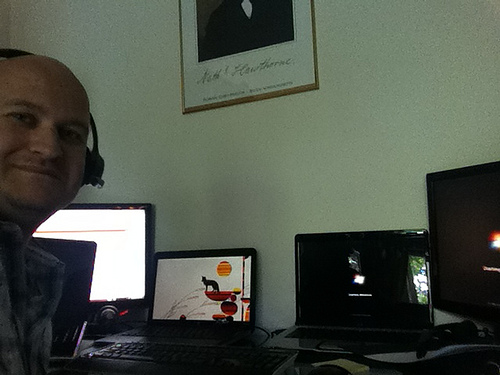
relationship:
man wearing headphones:
[4, 40, 87, 373] [1, 49, 105, 186]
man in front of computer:
[0, 40, 104, 375] [120, 237, 279, 358]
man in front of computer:
[0, 40, 104, 375] [271, 227, 447, 362]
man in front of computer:
[0, 40, 104, 375] [41, 218, 150, 365]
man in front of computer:
[0, 40, 104, 375] [35, 207, 150, 363]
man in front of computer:
[0, 40, 104, 375] [144, 247, 268, 372]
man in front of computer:
[0, 40, 104, 375] [279, 229, 457, 373]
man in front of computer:
[0, 40, 104, 375] [269, 222, 441, 358]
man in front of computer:
[0, 40, 104, 375] [92, 240, 262, 373]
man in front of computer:
[0, 40, 104, 375] [433, 171, 498, 323]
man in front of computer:
[0, 40, 104, 375] [254, 221, 439, 357]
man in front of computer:
[0, 40, 104, 375] [95, 243, 260, 350]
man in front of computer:
[0, 40, 104, 375] [33, 202, 153, 325]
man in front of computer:
[0, 40, 104, 375] [23, 236, 97, 363]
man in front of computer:
[0, 40, 104, 375] [426, 161, 498, 321]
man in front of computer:
[0, 40, 104, 375] [47, 189, 161, 343]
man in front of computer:
[0, 40, 104, 375] [274, 229, 416, 346]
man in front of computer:
[0, 40, 104, 375] [148, 234, 278, 366]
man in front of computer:
[0, 40, 104, 375] [408, 179, 485, 329]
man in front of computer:
[0, 40, 104, 375] [2, 200, 158, 353]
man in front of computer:
[0, 40, 104, 375] [115, 240, 272, 372]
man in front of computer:
[0, 40, 104, 375] [408, 157, 484, 372]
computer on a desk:
[262, 229, 435, 354] [27, 328, 489, 373]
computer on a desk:
[94, 247, 258, 347] [27, 328, 489, 373]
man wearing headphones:
[0, 40, 104, 375] [62, 81, 133, 200]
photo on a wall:
[178, 0, 320, 114] [350, 21, 495, 146]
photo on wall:
[178, 0, 320, 114] [0, 0, 499, 329]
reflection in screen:
[404, 252, 434, 310] [296, 229, 429, 326]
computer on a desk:
[264, 225, 439, 369] [13, 326, 498, 371]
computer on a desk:
[426, 156, 498, 363] [13, 326, 498, 371]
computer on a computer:
[83, 244, 261, 367] [25, 197, 155, 313]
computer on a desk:
[25, 197, 155, 313] [13, 326, 498, 371]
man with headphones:
[4, 40, 87, 373] [81, 106, 113, 202]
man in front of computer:
[4, 40, 87, 373] [37, 200, 154, 319]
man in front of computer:
[4, 40, 87, 373] [128, 239, 268, 344]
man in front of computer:
[4, 40, 87, 373] [271, 227, 447, 362]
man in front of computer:
[4, 40, 87, 373] [416, 157, 498, 349]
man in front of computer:
[4, 40, 87, 373] [134, 215, 256, 342]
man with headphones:
[4, 40, 87, 373] [1, 49, 105, 186]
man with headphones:
[0, 40, 104, 375] [1, 49, 105, 186]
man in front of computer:
[0, 40, 104, 375] [25, 197, 155, 313]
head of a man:
[1, 50, 98, 221] [1, 49, 119, 371]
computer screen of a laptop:
[152, 256, 251, 322] [87, 247, 262, 374]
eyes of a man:
[2, 91, 130, 163] [5, 32, 122, 279]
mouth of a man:
[11, 162, 68, 184] [0, 40, 104, 375]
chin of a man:
[4, 180, 75, 226] [0, 40, 104, 375]